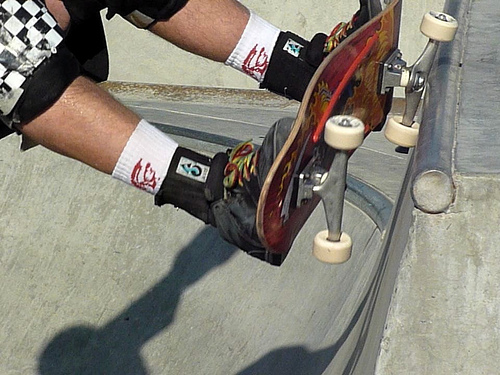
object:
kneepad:
[0, 0, 92, 109]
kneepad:
[107, 0, 198, 31]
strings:
[311, 16, 354, 53]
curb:
[330, 0, 500, 375]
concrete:
[0, 210, 381, 375]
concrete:
[381, 101, 500, 375]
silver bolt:
[295, 163, 329, 216]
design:
[127, 155, 163, 192]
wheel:
[415, 3, 465, 48]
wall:
[368, 45, 498, 375]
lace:
[213, 135, 269, 208]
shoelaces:
[318, 8, 357, 53]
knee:
[4, 0, 100, 112]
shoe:
[206, 116, 296, 271]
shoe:
[298, 0, 388, 102]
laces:
[307, 17, 351, 56]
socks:
[110, 117, 172, 204]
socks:
[224, 7, 276, 84]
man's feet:
[248, 0, 387, 109]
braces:
[215, 137, 264, 206]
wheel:
[317, 108, 373, 155]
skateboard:
[236, 1, 457, 269]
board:
[249, 0, 405, 256]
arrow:
[173, 154, 213, 186]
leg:
[0, 0, 214, 225]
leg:
[111, 0, 312, 94]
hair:
[182, 9, 207, 23]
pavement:
[0, 266, 500, 375]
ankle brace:
[152, 143, 225, 228]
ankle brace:
[256, 26, 313, 101]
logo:
[170, 153, 210, 183]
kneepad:
[0, 2, 83, 138]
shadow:
[35, 214, 237, 375]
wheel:
[309, 227, 357, 270]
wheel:
[378, 109, 426, 152]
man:
[2, 0, 385, 263]